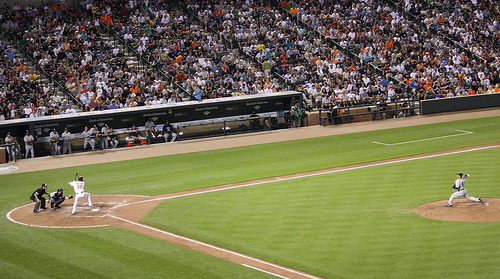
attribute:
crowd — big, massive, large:
[3, 0, 499, 120]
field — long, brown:
[4, 124, 499, 278]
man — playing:
[63, 167, 104, 218]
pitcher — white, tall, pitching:
[445, 169, 486, 211]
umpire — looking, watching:
[29, 180, 52, 215]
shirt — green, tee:
[293, 102, 307, 123]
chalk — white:
[124, 213, 311, 276]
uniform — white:
[66, 180, 95, 212]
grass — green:
[295, 202, 402, 274]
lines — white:
[114, 140, 493, 277]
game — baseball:
[8, 104, 494, 277]